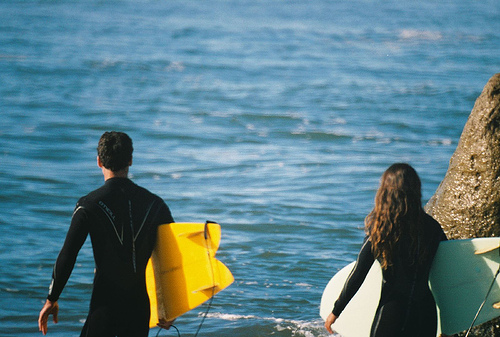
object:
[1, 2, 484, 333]
ocean water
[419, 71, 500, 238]
boulder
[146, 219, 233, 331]
board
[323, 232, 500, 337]
board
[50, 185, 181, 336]
suit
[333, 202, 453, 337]
suit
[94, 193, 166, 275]
design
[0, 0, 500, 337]
ocean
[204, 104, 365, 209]
waves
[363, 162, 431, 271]
hair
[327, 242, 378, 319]
arm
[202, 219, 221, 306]
strings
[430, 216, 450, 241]
arm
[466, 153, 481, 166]
holes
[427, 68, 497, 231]
rock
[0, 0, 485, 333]
water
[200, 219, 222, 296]
strap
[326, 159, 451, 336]
girl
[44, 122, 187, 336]
boy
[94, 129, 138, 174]
hair